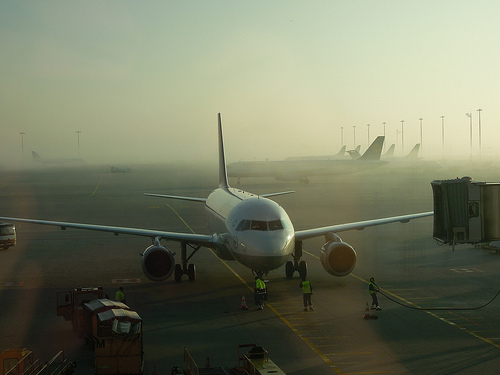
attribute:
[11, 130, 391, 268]
plane — shiny, still, large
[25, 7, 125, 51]
sky — misty, cloudy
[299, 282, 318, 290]
vest — reflective, yellow, green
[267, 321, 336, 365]
line — yellow, long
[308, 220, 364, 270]
engine — large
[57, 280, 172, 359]
wagon — large, orange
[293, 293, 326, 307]
pants — black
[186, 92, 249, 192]
tail — long, silver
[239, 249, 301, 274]
bottom — gray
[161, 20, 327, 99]
clouds — grey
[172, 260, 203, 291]
landing gear — large